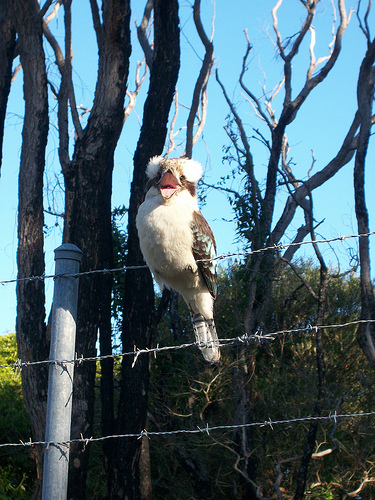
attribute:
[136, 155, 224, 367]
bird — motionless, white, chirping, brown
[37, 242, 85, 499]
pole — steel, metal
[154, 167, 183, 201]
beak — big, large, open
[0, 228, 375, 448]
fence — barbed wire, protective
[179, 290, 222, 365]
tail — long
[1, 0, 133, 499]
tree — leafless, dying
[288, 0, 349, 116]
branch — dry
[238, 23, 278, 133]
branch — dry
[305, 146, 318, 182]
branch — dry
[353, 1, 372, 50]
branch — dry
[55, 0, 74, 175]
branch — dry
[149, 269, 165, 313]
feather — folded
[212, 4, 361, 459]
tree — dying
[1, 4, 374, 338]
sky — cloudless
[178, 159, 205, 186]
feathers — white, fluffy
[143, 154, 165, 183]
feathers — white, fluffy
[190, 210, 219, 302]
feathers — striped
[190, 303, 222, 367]
feathers — striped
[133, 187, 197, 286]
feathers — white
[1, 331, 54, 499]
tree — green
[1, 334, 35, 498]
leaves — lush, green